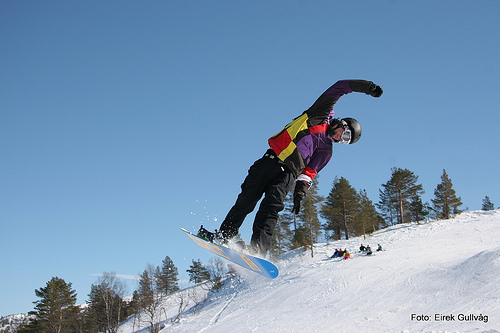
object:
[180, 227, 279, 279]
board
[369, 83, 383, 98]
gloved hand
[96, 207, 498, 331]
snow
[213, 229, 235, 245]
foot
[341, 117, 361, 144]
helmet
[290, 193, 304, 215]
hand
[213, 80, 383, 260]
athlete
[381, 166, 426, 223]
trees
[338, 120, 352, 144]
goggles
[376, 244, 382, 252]
skiers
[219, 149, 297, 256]
black pants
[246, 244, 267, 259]
foot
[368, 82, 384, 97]
gloves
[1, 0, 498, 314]
blue sky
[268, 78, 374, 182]
coat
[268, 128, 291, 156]
block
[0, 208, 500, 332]
mountain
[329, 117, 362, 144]
head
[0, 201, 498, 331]
hillside